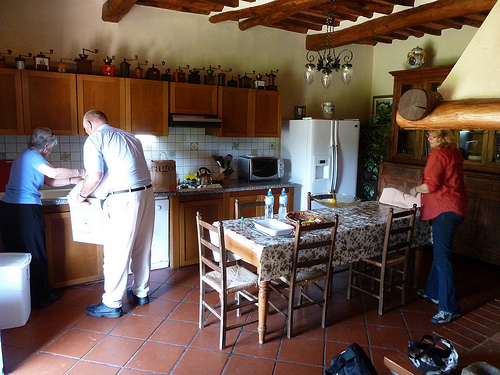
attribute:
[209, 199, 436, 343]
table — wooden, small, long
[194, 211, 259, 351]
chair — wooden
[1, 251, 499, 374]
tiles — red, terra-cotta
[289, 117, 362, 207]
refrigerator — white, upright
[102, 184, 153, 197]
belt — black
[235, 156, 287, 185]
microwave — silver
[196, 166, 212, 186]
tea kettle — silver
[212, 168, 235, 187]
knife block — wooden, wood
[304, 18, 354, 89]
light — hanging, black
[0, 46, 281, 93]
coffee grinders — old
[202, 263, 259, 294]
seat — wicker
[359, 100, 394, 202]
plant — fake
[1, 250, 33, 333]
trash can — white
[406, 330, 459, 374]
helmet — black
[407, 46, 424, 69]
jar — decorative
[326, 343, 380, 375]
bag — black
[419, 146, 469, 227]
shirt — red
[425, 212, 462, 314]
jeans — blue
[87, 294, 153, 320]
sneakers — black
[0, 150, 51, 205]
shirt — blue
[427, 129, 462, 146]
hair — blonde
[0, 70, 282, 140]
cabinets — brown